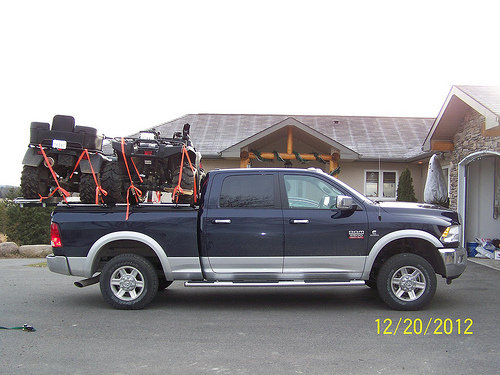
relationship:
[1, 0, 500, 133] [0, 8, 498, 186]
clouds in sky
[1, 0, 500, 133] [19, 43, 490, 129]
clouds are in sky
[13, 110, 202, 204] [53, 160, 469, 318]
wheelers are on back of truck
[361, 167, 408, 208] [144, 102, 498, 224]
windows are on building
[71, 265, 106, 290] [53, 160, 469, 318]
exhaust pipe on truck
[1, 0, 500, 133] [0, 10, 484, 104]
clouds are in sky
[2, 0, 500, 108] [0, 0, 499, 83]
white clouds are in sky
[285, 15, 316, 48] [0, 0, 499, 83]
white clouds are in sky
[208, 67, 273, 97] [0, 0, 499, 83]
white clouds are in sky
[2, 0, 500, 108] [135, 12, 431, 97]
white clouds are in sky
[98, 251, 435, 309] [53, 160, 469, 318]
tires on truck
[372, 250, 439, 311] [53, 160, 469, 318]
wheel on truck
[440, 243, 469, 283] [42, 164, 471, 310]
bumper on truck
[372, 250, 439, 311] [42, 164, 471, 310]
wheel on truck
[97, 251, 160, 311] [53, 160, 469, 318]
wheel on truck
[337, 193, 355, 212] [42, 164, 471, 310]
mirror on truck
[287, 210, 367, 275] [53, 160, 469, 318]
door panel on truck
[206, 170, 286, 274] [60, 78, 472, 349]
door panel on truck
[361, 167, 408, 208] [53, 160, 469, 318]
windows on truck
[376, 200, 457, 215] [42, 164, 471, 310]
hood on truck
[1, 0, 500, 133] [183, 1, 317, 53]
clouds in sky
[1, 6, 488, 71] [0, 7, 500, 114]
clouds in sky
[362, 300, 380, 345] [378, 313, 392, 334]
numbers one next to numbers two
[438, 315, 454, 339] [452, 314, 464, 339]
zero next to one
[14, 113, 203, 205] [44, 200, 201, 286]
atvs strapped into truck bed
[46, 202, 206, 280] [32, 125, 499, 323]
bed on truck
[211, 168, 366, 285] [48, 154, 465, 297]
cab on truck